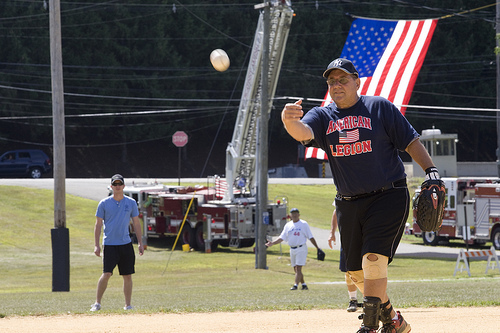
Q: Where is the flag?
A: Hanging behind the man.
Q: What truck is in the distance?
A: Fire truck.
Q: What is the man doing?
A: Throwing a ball.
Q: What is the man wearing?
A: Tshirt.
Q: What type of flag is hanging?
A: American flag.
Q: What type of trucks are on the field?
A: Fire trucks.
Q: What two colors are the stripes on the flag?
A: Red and white.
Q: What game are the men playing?
A: Baseball.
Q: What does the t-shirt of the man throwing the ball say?
A: American Legion.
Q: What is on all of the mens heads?
A: Baseball hats.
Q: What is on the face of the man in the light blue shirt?
A: Sun glasses.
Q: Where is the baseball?
A: In the air in front of closest man.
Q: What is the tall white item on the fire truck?
A: Ladder.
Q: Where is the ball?
A: In the air.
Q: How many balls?
A: 1.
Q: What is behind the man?
A: Fire trucks.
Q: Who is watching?
A: The guys.